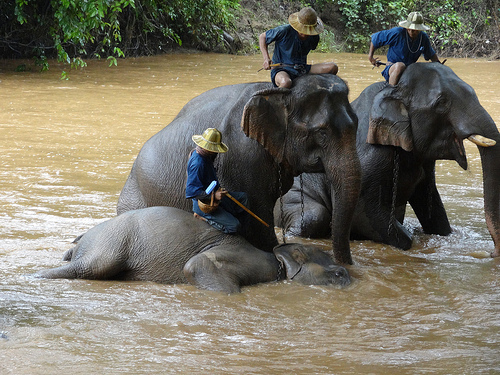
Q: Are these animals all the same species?
A: Yes, all the animals are elephants.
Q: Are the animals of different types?
A: No, all the animals are elephants.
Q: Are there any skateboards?
A: No, there are no skateboards.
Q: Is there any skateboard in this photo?
A: No, there are no skateboards.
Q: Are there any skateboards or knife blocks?
A: No, there are no skateboards or knife blocks.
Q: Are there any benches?
A: No, there are no benches.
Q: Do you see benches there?
A: No, there are no benches.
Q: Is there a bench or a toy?
A: No, there are no benches or toys.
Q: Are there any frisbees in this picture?
A: No, there are no frisbees.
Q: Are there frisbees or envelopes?
A: No, there are no frisbees or envelopes.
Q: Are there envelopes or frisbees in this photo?
A: No, there are no frisbees or envelopes.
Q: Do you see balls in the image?
A: No, there are no balls.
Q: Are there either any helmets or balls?
A: No, there are no balls or helmets.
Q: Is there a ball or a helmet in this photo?
A: No, there are no balls or helmets.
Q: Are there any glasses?
A: No, there are no glasses.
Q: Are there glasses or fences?
A: No, there are no glasses or fences.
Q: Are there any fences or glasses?
A: No, there are no glasses or fences.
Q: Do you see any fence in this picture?
A: No, there are no fences.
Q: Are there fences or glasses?
A: No, there are no fences or glasses.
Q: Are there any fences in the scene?
A: No, there are no fences.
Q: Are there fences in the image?
A: No, there are no fences.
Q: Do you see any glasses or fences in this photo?
A: No, there are no fences or glasses.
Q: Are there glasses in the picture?
A: No, there are no glasses.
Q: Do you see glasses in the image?
A: No, there are no glasses.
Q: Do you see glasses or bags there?
A: No, there are no glasses or bags.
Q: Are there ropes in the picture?
A: No, there are no ropes.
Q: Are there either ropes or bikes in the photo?
A: No, there are no ropes or bikes.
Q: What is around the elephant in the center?
A: The chains are around the elephant.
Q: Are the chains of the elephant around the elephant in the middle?
A: Yes, the chains are around the elephant.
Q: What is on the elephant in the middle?
A: The chains are on the elephant.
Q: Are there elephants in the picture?
A: Yes, there is an elephant.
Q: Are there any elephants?
A: Yes, there is an elephant.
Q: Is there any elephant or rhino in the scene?
A: Yes, there is an elephant.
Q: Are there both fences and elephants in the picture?
A: No, there is an elephant but no fences.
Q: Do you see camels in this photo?
A: No, there are no camels.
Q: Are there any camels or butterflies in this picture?
A: No, there are no camels or butterflies.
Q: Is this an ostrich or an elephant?
A: This is an elephant.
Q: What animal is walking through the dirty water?
A: The elephant is walking through the water.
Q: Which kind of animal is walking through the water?
A: The animal is an elephant.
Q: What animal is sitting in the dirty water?
A: The elephant is sitting in the water.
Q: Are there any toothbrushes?
A: No, there are no toothbrushes.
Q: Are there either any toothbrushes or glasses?
A: No, there are no toothbrushes or glasses.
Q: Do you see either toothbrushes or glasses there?
A: No, there are no toothbrushes or glasses.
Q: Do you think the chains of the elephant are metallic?
A: Yes, the chains are metallic.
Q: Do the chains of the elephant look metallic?
A: Yes, the chains are metallic.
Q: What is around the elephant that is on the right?
A: The chains are around the elephant.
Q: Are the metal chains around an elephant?
A: Yes, the chains are around an elephant.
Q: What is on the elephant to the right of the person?
A: The chains are on the elephant.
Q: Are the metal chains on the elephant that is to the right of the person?
A: Yes, the chains are on the elephant.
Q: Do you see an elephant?
A: Yes, there is an elephant.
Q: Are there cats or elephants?
A: Yes, there is an elephant.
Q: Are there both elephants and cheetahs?
A: No, there is an elephant but no cheetahs.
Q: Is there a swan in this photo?
A: No, there are no swans.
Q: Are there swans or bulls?
A: No, there are no swans or bulls.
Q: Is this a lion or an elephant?
A: This is an elephant.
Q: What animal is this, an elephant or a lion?
A: This is an elephant.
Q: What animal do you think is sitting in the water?
A: The elephant is sitting in the water.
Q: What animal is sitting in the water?
A: The elephant is sitting in the water.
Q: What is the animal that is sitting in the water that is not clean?
A: The animal is an elephant.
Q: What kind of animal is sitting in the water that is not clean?
A: The animal is an elephant.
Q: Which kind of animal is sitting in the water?
A: The animal is an elephant.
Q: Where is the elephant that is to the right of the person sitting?
A: The elephant is sitting in the water.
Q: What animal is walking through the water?
A: The elephant is walking through the water.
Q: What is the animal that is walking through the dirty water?
A: The animal is an elephant.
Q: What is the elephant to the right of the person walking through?
A: The elephant is walking through the water.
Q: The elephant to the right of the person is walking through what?
A: The elephant is walking through the water.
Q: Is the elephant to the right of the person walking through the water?
A: Yes, the elephant is walking through the water.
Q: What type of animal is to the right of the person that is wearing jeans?
A: The animal is an elephant.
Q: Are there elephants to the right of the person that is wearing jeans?
A: Yes, there is an elephant to the right of the person.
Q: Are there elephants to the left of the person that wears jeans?
A: No, the elephant is to the right of the person.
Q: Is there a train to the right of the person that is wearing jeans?
A: No, there is an elephant to the right of the person.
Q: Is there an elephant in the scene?
A: Yes, there is an elephant.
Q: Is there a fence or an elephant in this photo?
A: Yes, there is an elephant.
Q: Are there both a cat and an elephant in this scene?
A: No, there is an elephant but no cats.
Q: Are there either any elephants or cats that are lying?
A: Yes, the elephant is lying.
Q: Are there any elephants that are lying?
A: Yes, there is an elephant that is lying.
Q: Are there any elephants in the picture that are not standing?
A: Yes, there is an elephant that is lying.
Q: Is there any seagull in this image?
A: No, there are no seagulls.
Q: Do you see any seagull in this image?
A: No, there are no seagulls.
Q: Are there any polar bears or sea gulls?
A: No, there are no sea gulls or polar bears.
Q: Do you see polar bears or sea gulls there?
A: No, there are no sea gulls or polar bears.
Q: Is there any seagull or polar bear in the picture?
A: No, there are no seagulls or polar bears.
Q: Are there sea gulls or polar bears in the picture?
A: No, there are no sea gulls or polar bears.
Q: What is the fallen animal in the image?
A: The animal is an elephant.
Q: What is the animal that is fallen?
A: The animal is an elephant.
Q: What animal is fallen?
A: The animal is an elephant.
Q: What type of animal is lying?
A: The animal is an elephant.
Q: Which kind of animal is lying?
A: The animal is an elephant.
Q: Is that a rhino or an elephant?
A: That is an elephant.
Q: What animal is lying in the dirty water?
A: The elephant is lying in the water.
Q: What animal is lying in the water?
A: The elephant is lying in the water.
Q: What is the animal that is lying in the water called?
A: The animal is an elephant.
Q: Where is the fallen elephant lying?
A: The elephant is lying in the water.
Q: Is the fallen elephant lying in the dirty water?
A: Yes, the elephant is lying in the water.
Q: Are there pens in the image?
A: No, there are no pens.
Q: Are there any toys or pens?
A: No, there are no pens or toys.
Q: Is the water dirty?
A: Yes, the water is dirty.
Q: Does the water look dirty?
A: Yes, the water is dirty.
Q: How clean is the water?
A: The water is dirty.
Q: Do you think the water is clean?
A: No, the water is dirty.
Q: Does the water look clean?
A: No, the water is dirty.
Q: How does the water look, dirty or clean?
A: The water is dirty.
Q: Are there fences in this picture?
A: No, there are no fences.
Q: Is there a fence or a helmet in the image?
A: No, there are no fences or helmets.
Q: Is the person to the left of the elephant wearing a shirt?
A: Yes, the person is wearing a shirt.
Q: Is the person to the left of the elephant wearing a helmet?
A: No, the person is wearing a shirt.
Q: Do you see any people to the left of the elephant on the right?
A: Yes, there is a person to the left of the elephant.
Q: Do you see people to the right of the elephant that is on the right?
A: No, the person is to the left of the elephant.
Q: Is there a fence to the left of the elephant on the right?
A: No, there is a person to the left of the elephant.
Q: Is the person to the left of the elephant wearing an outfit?
A: Yes, the person is wearing an outfit.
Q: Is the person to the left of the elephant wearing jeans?
A: Yes, the person is wearing jeans.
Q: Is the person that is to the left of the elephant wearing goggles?
A: No, the person is wearing jeans.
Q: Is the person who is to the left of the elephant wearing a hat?
A: Yes, the person is wearing a hat.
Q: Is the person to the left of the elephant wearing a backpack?
A: No, the person is wearing a hat.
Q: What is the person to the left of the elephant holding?
A: The person is holding the stick.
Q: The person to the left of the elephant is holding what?
A: The person is holding the stick.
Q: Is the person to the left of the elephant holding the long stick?
A: Yes, the person is holding the stick.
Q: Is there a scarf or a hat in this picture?
A: Yes, there is a hat.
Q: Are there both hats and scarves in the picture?
A: No, there is a hat but no scarves.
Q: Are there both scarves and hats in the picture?
A: No, there is a hat but no scarves.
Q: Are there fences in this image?
A: No, there are no fences.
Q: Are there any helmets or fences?
A: No, there are no fences or helmets.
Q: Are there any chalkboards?
A: No, there are no chalkboards.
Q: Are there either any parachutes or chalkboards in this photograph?
A: No, there are no chalkboards or parachutes.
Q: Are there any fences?
A: No, there are no fences.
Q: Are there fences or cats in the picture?
A: No, there are no fences or cats.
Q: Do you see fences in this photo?
A: No, there are no fences.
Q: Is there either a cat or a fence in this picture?
A: No, there are no fences or cats.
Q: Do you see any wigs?
A: No, there are no wigs.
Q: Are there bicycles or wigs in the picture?
A: No, there are no wigs or bicycles.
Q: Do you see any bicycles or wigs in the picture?
A: No, there are no wigs or bicycles.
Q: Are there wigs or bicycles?
A: No, there are no wigs or bicycles.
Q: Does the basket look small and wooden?
A: Yes, the basket is small and wooden.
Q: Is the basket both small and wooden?
A: Yes, the basket is small and wooden.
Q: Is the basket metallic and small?
A: No, the basket is small but wooden.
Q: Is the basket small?
A: Yes, the basket is small.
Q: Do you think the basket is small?
A: Yes, the basket is small.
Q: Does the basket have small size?
A: Yes, the basket is small.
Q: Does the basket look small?
A: Yes, the basket is small.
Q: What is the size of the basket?
A: The basket is small.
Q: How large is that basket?
A: The basket is small.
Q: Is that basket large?
A: No, the basket is small.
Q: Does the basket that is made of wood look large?
A: No, the basket is small.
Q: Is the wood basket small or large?
A: The basket is small.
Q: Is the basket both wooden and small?
A: Yes, the basket is wooden and small.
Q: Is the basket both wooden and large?
A: No, the basket is wooden but small.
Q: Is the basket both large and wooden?
A: No, the basket is wooden but small.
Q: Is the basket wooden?
A: Yes, the basket is wooden.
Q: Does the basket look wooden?
A: Yes, the basket is wooden.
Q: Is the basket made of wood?
A: Yes, the basket is made of wood.